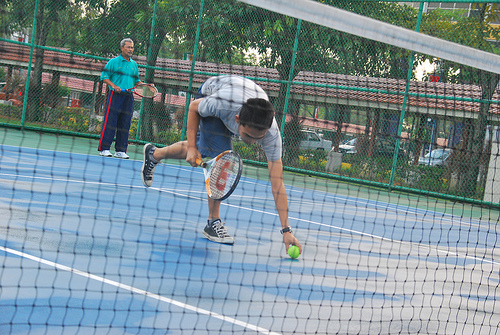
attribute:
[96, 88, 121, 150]
leg — side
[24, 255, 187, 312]
line — white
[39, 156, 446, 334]
court — white, blue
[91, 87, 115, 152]
stripe — red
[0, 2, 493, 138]
fence — chain link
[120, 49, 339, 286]
man — bending, reaching, leaning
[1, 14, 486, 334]
net — black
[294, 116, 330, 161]
car — white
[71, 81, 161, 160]
pants — blue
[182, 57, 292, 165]
shirt — gray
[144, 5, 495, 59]
leaves — green